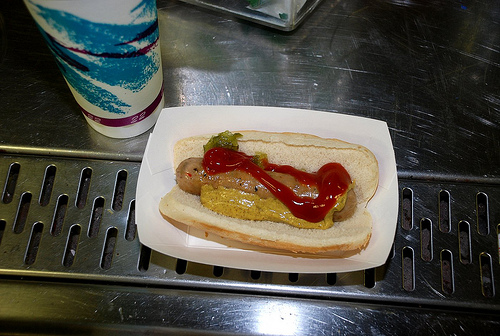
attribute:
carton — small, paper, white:
[134, 103, 402, 275]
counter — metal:
[0, 2, 499, 335]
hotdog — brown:
[175, 155, 358, 222]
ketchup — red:
[203, 148, 351, 226]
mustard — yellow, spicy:
[198, 182, 359, 234]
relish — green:
[201, 128, 268, 171]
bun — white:
[157, 130, 380, 256]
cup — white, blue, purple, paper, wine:
[24, 1, 165, 141]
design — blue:
[30, 1, 162, 116]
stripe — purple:
[65, 81, 174, 130]